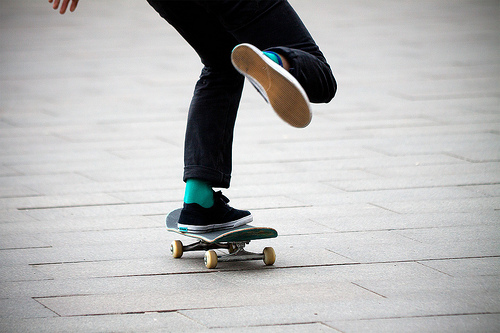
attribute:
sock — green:
[182, 180, 218, 210]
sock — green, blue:
[262, 45, 282, 66]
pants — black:
[147, 2, 336, 188]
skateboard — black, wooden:
[167, 205, 278, 270]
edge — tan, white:
[164, 226, 278, 243]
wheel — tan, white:
[202, 249, 218, 269]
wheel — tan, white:
[264, 247, 277, 265]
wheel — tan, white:
[169, 240, 185, 260]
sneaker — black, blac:
[178, 189, 253, 233]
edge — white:
[178, 214, 255, 232]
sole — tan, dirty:
[231, 45, 311, 128]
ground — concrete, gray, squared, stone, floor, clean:
[3, 1, 497, 328]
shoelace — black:
[218, 188, 230, 204]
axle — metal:
[218, 243, 266, 262]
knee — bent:
[325, 73, 340, 104]